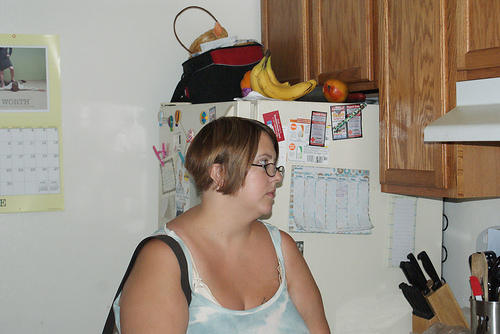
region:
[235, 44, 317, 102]
Bananas on top of fridge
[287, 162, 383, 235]
Calendar on side of refrigerator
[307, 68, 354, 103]
Apple next to banana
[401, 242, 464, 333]
Knives in wooden container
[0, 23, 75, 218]
Yellow and white calendar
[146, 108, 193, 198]
Magnets on the front of the fridge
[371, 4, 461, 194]
Wooden kitchen cupboard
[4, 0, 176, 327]
Wall covered in white paint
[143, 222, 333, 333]
Woman's tank top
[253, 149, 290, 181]
Black glases on woman's face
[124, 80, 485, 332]
A person in the kitchen.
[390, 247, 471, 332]
A set of knives.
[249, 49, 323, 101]
A bunch of bananas.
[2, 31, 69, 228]
A calendar on the kitchen wall.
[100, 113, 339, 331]
A lady wearing a purse on her shoulder.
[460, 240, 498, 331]
A bunch of kitchen utensils.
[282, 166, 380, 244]
A weekly calendar on the refrigerator.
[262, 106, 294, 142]
A magnet on the refrigerator.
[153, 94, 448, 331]
A refrigerator.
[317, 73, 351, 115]
An orange on top of the refrigerator.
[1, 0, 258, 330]
open calendar hanging on wall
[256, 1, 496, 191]
overhead wooden cabinets attached to wall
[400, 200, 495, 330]
knives and utensils in separate containers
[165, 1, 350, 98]
bag, basket and fruit on top of refrigerator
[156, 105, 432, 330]
magnets and papers attached to refrigerator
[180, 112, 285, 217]
woman with lowered eyeglasses looking to side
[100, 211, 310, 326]
black strap over white tank top over a brassiere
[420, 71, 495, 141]
extended panel of exhaust fan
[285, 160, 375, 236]
pad of paper with curled corners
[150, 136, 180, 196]
pink clip attached to note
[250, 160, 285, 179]
Low-profile reading glasses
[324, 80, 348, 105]
Apple sitting on top of the refrigerator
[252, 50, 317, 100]
Bananas sitting on top of the refrigerator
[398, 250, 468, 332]
Set of knives sitting on the counter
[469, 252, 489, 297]
Large wooden cooking spoon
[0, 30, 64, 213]
Calendar hanging on the wall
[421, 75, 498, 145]
Exhaust fan for cooking surface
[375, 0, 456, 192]
Door on overhead storage area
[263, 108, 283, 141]
Magnet stuck to side of refrigerator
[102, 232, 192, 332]
Black purse strap worn on the shoulder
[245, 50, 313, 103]
yellow bananas on a refrigerator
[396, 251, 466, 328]
a wooden knife holder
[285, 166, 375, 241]
a paper on the refrigerator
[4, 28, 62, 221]
a calendar on the wall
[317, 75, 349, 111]
a apple on the refrigerator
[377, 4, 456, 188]
a brown wooden cabinet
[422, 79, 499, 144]
a white vent hood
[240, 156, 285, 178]
a pair of black framed glasses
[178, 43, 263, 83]
a book on the refrigerator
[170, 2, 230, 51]
a basket on the refrigerator